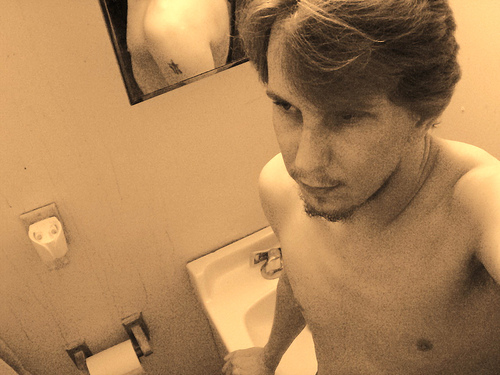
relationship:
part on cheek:
[332, 169, 372, 183] [342, 133, 402, 193]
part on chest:
[335, 241, 395, 294] [266, 188, 496, 373]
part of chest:
[389, 261, 431, 299] [291, 250, 418, 361]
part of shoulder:
[449, 151, 489, 181] [435, 139, 498, 253]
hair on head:
[241, 0, 468, 118] [227, 0, 462, 224]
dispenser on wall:
[20, 216, 70, 262] [4, 0, 499, 370]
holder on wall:
[80, 310, 167, 372] [18, 54, 248, 244]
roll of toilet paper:
[92, 350, 139, 372] [35, 310, 127, 373]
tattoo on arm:
[166, 58, 183, 76] [145, 30, 235, 90]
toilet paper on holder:
[84, 337, 148, 375] [61, 303, 157, 367]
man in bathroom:
[222, 1, 499, 373] [0, 1, 498, 373]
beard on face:
[293, 170, 390, 221] [268, 87, 402, 221]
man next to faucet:
[222, 1, 499, 373] [244, 242, 288, 283]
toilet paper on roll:
[84, 338, 148, 373] [76, 330, 143, 373]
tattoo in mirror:
[163, 56, 181, 77] [101, 17, 250, 107]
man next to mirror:
[222, 1, 499, 373] [99, 0, 264, 106]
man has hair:
[222, 1, 499, 373] [241, 0, 468, 118]